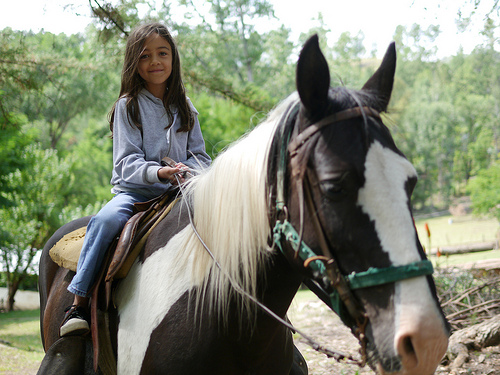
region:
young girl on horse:
[43, 24, 451, 374]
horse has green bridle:
[271, 82, 451, 373]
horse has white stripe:
[351, 147, 450, 373]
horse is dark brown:
[46, 49, 453, 372]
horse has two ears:
[303, 34, 400, 117]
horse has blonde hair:
[192, 101, 294, 316]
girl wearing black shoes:
[54, 18, 214, 335]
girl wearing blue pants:
[78, 24, 208, 332]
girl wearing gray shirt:
[80, 28, 202, 320]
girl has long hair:
[108, 21, 196, 134]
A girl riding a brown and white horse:
[8, 7, 474, 368]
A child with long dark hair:
[53, 14, 221, 341]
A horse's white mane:
[181, 89, 317, 334]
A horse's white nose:
[387, 302, 459, 372]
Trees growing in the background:
[420, 61, 499, 218]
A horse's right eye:
[311, 161, 361, 203]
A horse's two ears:
[279, 19, 416, 127]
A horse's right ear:
[279, 27, 348, 128]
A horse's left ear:
[353, 30, 413, 116]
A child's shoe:
[45, 288, 101, 340]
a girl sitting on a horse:
[36, 20, 454, 371]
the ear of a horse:
[289, 33, 345, 117]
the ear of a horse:
[362, 36, 402, 118]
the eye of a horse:
[313, 163, 348, 210]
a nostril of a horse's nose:
[391, 332, 421, 367]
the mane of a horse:
[183, 120, 283, 335]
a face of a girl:
[134, 40, 182, 82]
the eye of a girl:
[156, 45, 173, 61]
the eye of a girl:
[134, 46, 154, 62]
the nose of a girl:
[145, 50, 164, 75]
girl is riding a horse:
[37, 13, 457, 371]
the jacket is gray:
[100, 71, 209, 204]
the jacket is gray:
[79, 83, 255, 273]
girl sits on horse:
[68, 37, 213, 268]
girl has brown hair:
[107, 0, 194, 120]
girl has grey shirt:
[75, 85, 197, 207]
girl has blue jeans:
[31, 204, 168, 308]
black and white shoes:
[37, 310, 112, 352]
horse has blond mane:
[185, 123, 280, 298]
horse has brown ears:
[284, 34, 405, 128]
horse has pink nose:
[385, 315, 442, 373]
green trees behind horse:
[15, 43, 497, 214]